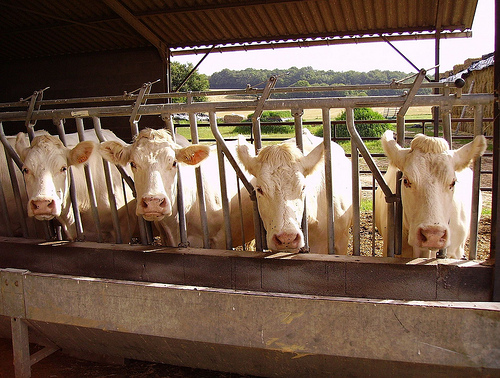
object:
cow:
[97, 128, 267, 252]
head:
[99, 130, 210, 222]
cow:
[13, 128, 159, 244]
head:
[13, 132, 94, 221]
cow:
[237, 127, 352, 256]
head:
[236, 133, 325, 254]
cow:
[373, 130, 487, 259]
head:
[381, 128, 486, 251]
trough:
[2, 237, 499, 378]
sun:
[475, 5, 494, 23]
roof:
[3, 1, 477, 59]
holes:
[62, 117, 103, 243]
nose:
[138, 195, 168, 212]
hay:
[439, 66, 496, 138]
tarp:
[438, 54, 495, 84]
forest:
[208, 70, 231, 94]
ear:
[175, 144, 210, 165]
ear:
[98, 140, 131, 166]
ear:
[66, 140, 95, 166]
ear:
[298, 141, 324, 177]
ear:
[235, 133, 258, 176]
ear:
[381, 129, 412, 171]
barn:
[4, 2, 479, 242]